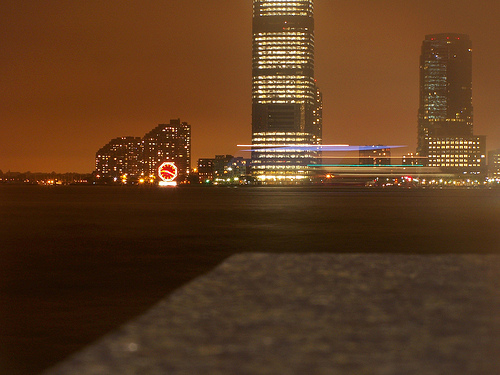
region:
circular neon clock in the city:
[149, 159, 184, 189]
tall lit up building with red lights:
[406, 23, 476, 179]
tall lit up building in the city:
[237, 5, 335, 217]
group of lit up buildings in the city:
[70, 110, 207, 197]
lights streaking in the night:
[231, 131, 445, 191]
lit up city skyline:
[71, 21, 493, 213]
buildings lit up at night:
[70, 114, 255, 200]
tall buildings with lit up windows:
[231, 13, 341, 208]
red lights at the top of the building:
[396, 19, 481, 59]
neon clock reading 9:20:
[149, 156, 179, 196]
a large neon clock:
[141, 149, 183, 198]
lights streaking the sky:
[221, 123, 466, 206]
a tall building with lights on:
[217, 2, 349, 191]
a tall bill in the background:
[402, 28, 499, 188]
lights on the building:
[252, 23, 312, 75]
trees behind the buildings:
[0, 162, 108, 189]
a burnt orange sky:
[16, 15, 189, 106]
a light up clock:
[152, 152, 182, 190]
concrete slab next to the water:
[35, 210, 497, 367]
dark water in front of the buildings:
[55, 195, 162, 261]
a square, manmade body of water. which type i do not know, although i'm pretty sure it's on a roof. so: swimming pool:
[20, 252, 498, 372]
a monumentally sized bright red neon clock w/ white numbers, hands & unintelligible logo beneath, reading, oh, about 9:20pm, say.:
[150, 155, 180, 185]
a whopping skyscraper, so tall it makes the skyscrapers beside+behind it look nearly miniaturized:
[240, 0, 320, 190]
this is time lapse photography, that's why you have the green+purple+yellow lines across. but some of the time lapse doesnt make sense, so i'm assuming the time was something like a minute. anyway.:
[47, 115, 497, 210]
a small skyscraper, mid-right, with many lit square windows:
[420, 132, 487, 182]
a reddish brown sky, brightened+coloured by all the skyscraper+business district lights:
[0, 1, 498, 183]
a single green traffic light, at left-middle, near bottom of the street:
[201, 178, 211, 185]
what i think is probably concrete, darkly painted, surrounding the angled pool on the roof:
[0, 183, 499, 373]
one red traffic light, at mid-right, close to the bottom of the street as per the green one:
[402, 175, 415, 188]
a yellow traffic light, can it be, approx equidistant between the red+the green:
[321, 168, 336, 183]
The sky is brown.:
[49, 11, 194, 91]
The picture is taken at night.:
[1, 1, 498, 373]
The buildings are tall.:
[244, 0, 495, 203]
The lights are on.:
[243, 3, 497, 185]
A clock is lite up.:
[148, 155, 184, 188]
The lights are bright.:
[80, 1, 498, 191]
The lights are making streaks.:
[228, 125, 461, 183]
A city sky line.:
[63, 2, 498, 193]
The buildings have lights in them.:
[63, 4, 499, 192]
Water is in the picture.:
[114, 197, 392, 235]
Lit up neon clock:
[154, 159, 185, 191]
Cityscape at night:
[74, 7, 470, 196]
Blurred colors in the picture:
[228, 136, 437, 188]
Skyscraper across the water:
[244, 0, 328, 187]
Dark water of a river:
[17, 193, 191, 256]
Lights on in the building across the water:
[254, 74, 309, 102]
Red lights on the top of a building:
[425, 31, 467, 43]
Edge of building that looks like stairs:
[142, 114, 170, 145]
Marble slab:
[227, 244, 497, 369]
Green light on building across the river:
[203, 174, 211, 187]